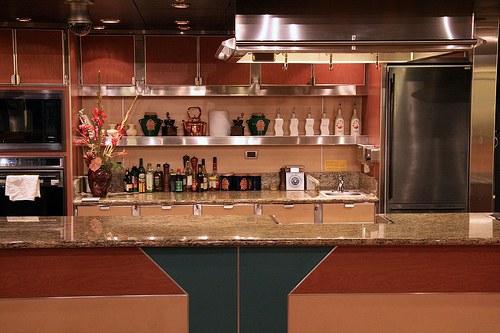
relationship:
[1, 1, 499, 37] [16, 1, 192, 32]
ceiling has recessed lighting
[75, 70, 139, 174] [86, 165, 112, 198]
flowers in vase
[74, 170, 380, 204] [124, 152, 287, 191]
counter has condiments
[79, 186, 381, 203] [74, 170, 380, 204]
reflection on counter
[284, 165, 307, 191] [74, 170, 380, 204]
scale on counter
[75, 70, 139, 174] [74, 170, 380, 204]
flowers on counter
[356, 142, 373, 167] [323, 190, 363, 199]
silver box near sink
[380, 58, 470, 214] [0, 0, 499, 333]
refrigerator in kitchen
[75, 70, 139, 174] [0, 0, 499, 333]
flowers in kitchen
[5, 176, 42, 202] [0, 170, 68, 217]
kitchen towel on oven door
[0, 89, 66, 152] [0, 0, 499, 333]
microwave in kitchen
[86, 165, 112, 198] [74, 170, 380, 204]
vase on counter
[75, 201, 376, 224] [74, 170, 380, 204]
drawers under counter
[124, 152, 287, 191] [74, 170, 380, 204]
condiments on counter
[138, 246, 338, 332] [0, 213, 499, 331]
blue on counter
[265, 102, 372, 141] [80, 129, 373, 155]
bottles on shelf